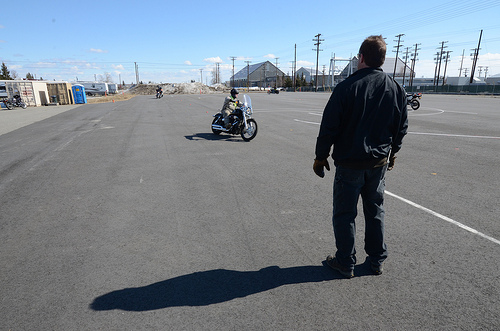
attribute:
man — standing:
[309, 32, 409, 279]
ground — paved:
[1, 95, 499, 331]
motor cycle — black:
[205, 104, 261, 143]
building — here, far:
[230, 59, 286, 89]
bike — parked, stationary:
[153, 85, 166, 103]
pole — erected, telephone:
[311, 30, 324, 91]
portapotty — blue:
[72, 83, 91, 106]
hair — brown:
[358, 34, 386, 67]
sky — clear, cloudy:
[1, 1, 499, 84]